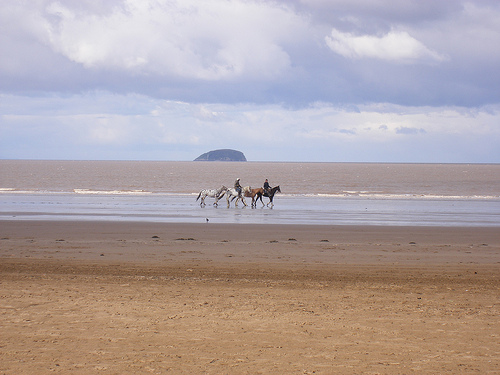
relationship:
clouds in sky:
[29, 0, 307, 78] [1, 1, 499, 163]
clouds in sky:
[323, 26, 445, 68] [1, 1, 499, 163]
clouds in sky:
[250, 102, 452, 135] [1, 1, 499, 163]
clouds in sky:
[49, 102, 158, 144] [1, 1, 499, 163]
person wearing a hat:
[233, 176, 243, 197] [235, 173, 243, 183]